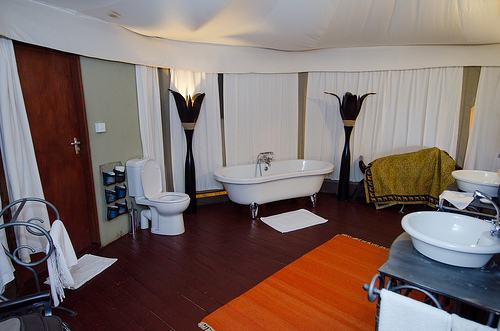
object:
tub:
[212, 159, 333, 220]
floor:
[56, 216, 396, 330]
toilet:
[125, 155, 192, 236]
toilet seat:
[151, 193, 190, 205]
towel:
[47, 217, 77, 308]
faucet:
[472, 189, 500, 223]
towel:
[259, 209, 329, 234]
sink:
[451, 170, 499, 197]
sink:
[400, 210, 500, 270]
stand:
[376, 264, 497, 298]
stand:
[440, 188, 498, 210]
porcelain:
[125, 158, 145, 197]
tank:
[149, 192, 190, 236]